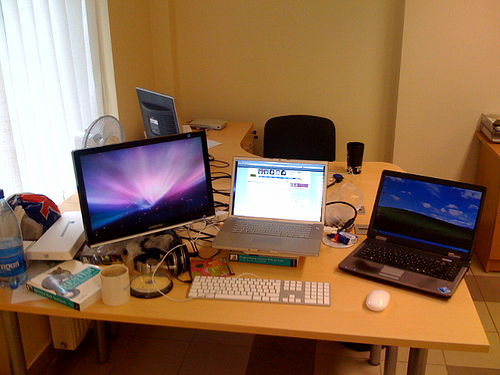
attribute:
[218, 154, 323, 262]
laptop — silver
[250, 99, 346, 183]
chair — black, empty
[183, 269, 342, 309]
keyboard — white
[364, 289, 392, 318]
mouse — white